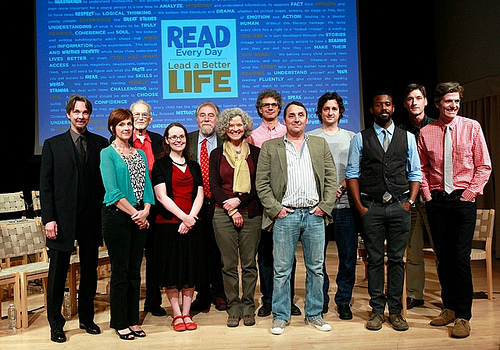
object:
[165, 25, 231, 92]
sign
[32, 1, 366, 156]
screen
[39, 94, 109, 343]
man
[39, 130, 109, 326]
suit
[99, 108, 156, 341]
woman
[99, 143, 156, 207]
sweater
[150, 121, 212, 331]
woman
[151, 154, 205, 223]
shirt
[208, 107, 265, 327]
woman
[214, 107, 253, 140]
hair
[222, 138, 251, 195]
scarf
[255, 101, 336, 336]
man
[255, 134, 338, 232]
jacket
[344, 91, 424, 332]
man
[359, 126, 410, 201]
vest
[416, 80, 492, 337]
man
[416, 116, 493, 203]
shirt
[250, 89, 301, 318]
man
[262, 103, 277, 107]
glasses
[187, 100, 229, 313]
man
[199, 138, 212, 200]
tie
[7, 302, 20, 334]
water bottle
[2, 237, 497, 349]
floor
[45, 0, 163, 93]
words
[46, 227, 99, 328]
pants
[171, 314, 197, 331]
shoes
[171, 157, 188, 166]
necklace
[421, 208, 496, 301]
chair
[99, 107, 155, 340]
people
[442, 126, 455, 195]
tie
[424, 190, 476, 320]
pants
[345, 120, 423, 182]
shirt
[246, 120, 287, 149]
shirt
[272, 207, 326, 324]
jeans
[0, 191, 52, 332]
chair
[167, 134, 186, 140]
glasses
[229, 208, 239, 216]
bracelet